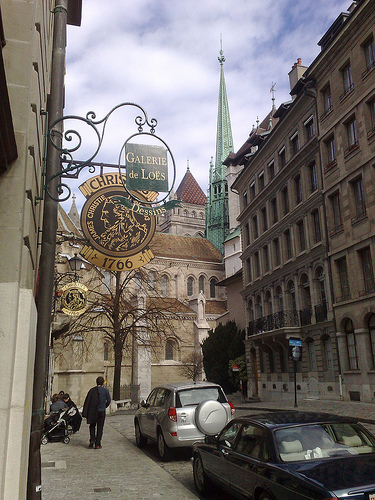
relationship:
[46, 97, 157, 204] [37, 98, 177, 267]
brace for sign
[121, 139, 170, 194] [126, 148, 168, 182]
sign has lettering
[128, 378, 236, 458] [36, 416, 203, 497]
car next to sidewalk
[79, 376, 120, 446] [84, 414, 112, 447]
man wearing pants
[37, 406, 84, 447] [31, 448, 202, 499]
carriege on sidewalk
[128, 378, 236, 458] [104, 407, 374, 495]
car parked on street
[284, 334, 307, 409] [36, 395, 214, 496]
signal on sidewalk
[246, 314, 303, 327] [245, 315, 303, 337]
fence on balcony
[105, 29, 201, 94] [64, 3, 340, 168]
clouds in sky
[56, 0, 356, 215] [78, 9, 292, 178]
clouds in sky